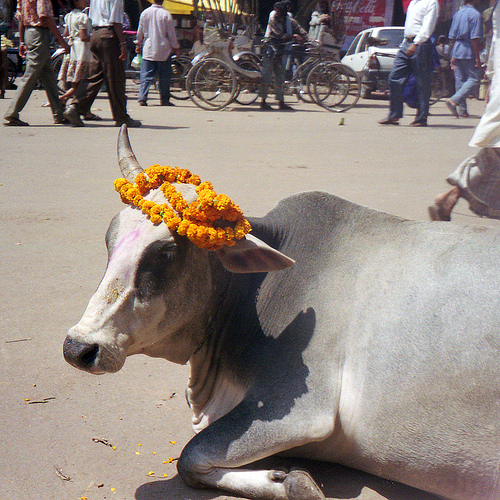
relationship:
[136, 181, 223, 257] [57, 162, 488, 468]
flower on animal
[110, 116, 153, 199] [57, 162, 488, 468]
horn on animal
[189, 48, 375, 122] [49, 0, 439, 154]
bicycle on background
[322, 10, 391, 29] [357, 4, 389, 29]
advertising for coke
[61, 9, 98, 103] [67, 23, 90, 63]
woman in dress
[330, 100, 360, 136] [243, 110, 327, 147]
flower on ground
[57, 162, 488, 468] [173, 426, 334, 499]
animal has leg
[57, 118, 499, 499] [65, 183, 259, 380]
animal has head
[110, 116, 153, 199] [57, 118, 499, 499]
horn on animal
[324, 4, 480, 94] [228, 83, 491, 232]
shop by road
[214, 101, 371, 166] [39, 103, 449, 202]
debris in street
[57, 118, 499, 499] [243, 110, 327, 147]
animal on ground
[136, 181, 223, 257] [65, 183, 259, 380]
flower on head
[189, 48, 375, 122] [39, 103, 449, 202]
bicycle on street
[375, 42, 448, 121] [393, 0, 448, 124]
jeans on man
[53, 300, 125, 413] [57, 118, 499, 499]
nose on animal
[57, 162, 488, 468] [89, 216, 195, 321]
animal has eyes